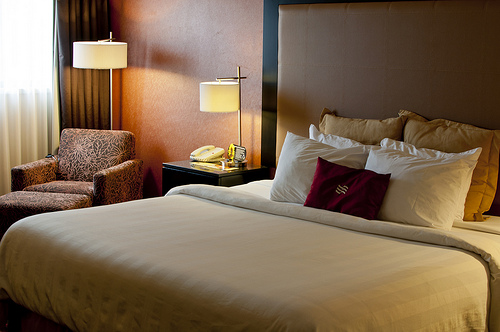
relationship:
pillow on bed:
[302, 156, 392, 220] [14, 169, 484, 329]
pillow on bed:
[369, 144, 478, 233] [13, 146, 483, 327]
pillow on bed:
[268, 131, 369, 205] [43, 157, 483, 308]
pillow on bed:
[264, 130, 366, 207] [28, 164, 443, 328]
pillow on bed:
[301, 153, 395, 220] [4, 170, 478, 309]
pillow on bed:
[268, 131, 369, 205] [14, 169, 484, 329]